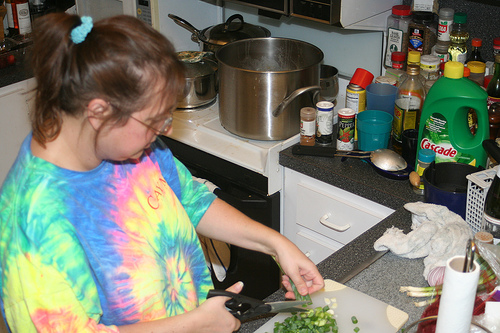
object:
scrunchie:
[68, 16, 93, 45]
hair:
[29, 16, 64, 114]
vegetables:
[272, 290, 359, 333]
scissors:
[205, 289, 310, 322]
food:
[266, 255, 360, 332]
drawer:
[295, 183, 384, 247]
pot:
[214, 36, 324, 141]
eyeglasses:
[107, 101, 173, 135]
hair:
[78, 41, 155, 84]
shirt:
[0, 133, 219, 333]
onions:
[272, 300, 336, 333]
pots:
[166, 13, 273, 62]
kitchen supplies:
[167, 0, 500, 284]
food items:
[300, 5, 498, 195]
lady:
[2, 3, 330, 331]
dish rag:
[373, 200, 473, 278]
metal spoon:
[292, 145, 407, 171]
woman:
[0, 10, 323, 333]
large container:
[414, 61, 490, 179]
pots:
[168, 49, 220, 109]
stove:
[320, 64, 339, 102]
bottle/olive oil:
[391, 64, 426, 154]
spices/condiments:
[296, 0, 500, 195]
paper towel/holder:
[434, 255, 481, 333]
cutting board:
[253, 276, 409, 333]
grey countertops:
[316, 249, 381, 281]